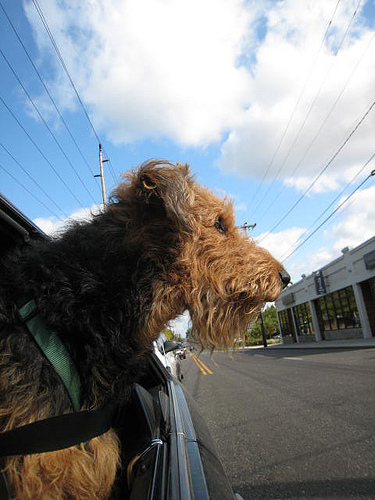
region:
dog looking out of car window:
[5, 149, 303, 465]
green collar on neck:
[23, 306, 91, 390]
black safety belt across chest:
[15, 404, 109, 460]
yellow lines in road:
[187, 346, 217, 381]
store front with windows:
[281, 258, 353, 356]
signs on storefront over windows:
[278, 269, 335, 305]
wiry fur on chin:
[194, 293, 263, 348]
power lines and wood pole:
[48, 84, 108, 185]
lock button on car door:
[132, 444, 214, 495]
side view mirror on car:
[157, 334, 182, 358]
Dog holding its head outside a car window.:
[0, 167, 333, 497]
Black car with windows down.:
[134, 353, 248, 497]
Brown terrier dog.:
[74, 143, 300, 383]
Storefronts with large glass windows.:
[260, 264, 374, 337]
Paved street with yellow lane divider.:
[183, 343, 374, 493]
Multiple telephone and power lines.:
[231, 107, 374, 258]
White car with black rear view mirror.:
[154, 331, 189, 380]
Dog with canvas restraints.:
[1, 201, 179, 472]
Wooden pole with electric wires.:
[80, 123, 119, 206]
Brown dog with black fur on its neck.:
[27, 138, 317, 435]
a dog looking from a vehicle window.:
[34, 121, 359, 486]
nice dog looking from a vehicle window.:
[24, 139, 336, 465]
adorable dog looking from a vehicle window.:
[32, 129, 339, 463]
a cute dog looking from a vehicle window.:
[29, 141, 347, 458]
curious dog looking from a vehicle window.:
[21, 150, 335, 468]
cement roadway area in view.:
[219, 377, 358, 476]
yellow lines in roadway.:
[191, 351, 218, 388]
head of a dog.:
[93, 157, 304, 351]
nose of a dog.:
[265, 259, 299, 308]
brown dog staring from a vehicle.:
[81, 169, 307, 470]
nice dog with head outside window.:
[32, 125, 308, 410]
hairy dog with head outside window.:
[10, 133, 322, 406]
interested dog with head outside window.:
[53, 159, 327, 428]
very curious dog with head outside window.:
[35, 131, 325, 405]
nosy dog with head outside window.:
[27, 157, 313, 475]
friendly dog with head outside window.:
[33, 91, 327, 440]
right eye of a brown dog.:
[204, 204, 235, 244]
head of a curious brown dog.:
[89, 141, 291, 339]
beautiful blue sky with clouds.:
[99, 24, 278, 136]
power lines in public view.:
[1, 34, 103, 194]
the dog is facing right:
[5, 153, 288, 493]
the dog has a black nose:
[279, 270, 292, 283]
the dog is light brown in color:
[1, 159, 291, 498]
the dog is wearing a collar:
[19, 290, 110, 429]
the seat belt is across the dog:
[1, 394, 117, 461]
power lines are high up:
[0, 3, 127, 228]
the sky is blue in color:
[1, 2, 373, 320]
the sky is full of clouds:
[16, 1, 373, 193]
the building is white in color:
[270, 233, 373, 345]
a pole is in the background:
[231, 220, 274, 349]